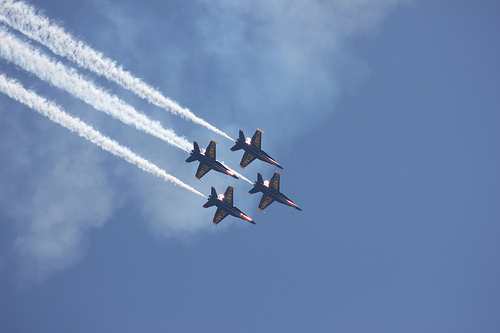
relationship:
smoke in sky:
[0, 1, 253, 198] [3, 5, 499, 330]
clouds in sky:
[183, 25, 315, 99] [316, 77, 486, 321]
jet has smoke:
[230, 128, 282, 169] [0, 1, 182, 199]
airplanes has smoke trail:
[247, 171, 302, 215] [0, 24, 253, 185]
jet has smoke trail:
[203, 185, 256, 227] [2, 73, 208, 198]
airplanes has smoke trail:
[247, 171, 302, 215] [0, 25, 194, 152]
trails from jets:
[15, 30, 184, 190] [155, 113, 269, 217]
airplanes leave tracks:
[184, 129, 300, 233] [0, 0, 197, 195]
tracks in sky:
[0, 0, 197, 195] [3, 5, 499, 330]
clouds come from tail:
[30, 25, 142, 153] [242, 170, 265, 197]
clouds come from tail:
[30, 25, 142, 153] [224, 121, 244, 152]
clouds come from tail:
[30, 25, 142, 153] [176, 137, 200, 165]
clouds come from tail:
[30, 25, 142, 153] [197, 180, 219, 209]